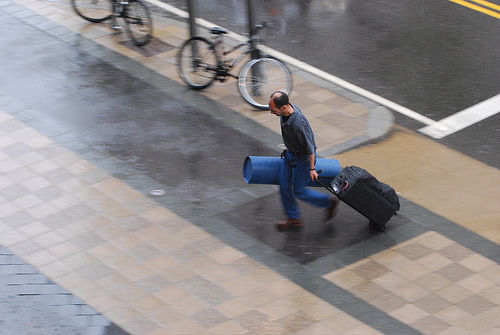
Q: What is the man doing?
A: Carrying a case and pulling a suitcase.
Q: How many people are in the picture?
A: One.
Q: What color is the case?
A: Blue.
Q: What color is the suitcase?
A: Black.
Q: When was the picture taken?
A: During the day.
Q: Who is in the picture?
A: A man.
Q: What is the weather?
A: Rainy.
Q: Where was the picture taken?
A: Over a city sidewalk.